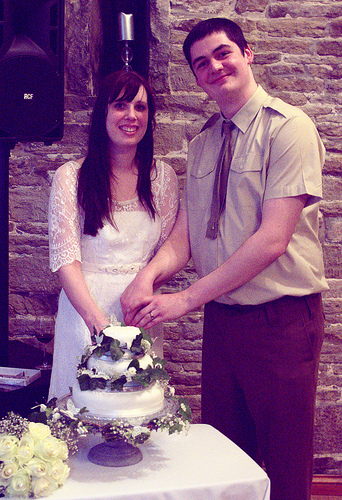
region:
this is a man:
[156, 23, 340, 302]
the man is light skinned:
[212, 250, 263, 298]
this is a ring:
[148, 311, 156, 321]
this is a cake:
[78, 312, 182, 432]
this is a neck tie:
[207, 139, 228, 215]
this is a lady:
[60, 58, 182, 449]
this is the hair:
[83, 142, 101, 198]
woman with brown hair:
[78, 52, 159, 224]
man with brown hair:
[170, 12, 260, 110]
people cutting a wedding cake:
[58, 308, 182, 434]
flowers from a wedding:
[0, 401, 81, 495]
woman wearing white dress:
[31, 75, 186, 384]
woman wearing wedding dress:
[42, 50, 185, 375]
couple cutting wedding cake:
[25, 8, 324, 377]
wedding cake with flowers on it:
[50, 300, 201, 462]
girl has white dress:
[65, 153, 171, 389]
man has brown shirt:
[176, 103, 332, 318]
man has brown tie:
[204, 106, 246, 258]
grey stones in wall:
[254, 1, 339, 76]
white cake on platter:
[27, 321, 197, 440]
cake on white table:
[32, 328, 187, 473]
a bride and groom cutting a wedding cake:
[50, 15, 322, 464]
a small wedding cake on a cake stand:
[56, 322, 181, 467]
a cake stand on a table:
[58, 393, 179, 468]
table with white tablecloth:
[30, 422, 269, 498]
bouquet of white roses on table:
[2, 413, 70, 498]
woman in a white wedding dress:
[48, 72, 178, 397]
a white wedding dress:
[50, 159, 179, 398]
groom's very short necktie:
[209, 122, 246, 238]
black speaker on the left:
[5, 5, 66, 144]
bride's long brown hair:
[80, 71, 157, 236]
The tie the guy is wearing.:
[204, 118, 236, 235]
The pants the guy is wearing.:
[193, 303, 322, 489]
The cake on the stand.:
[62, 319, 173, 415]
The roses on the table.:
[0, 416, 62, 497]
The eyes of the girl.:
[112, 103, 143, 108]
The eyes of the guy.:
[192, 48, 232, 69]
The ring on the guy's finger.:
[149, 310, 157, 318]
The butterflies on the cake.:
[51, 321, 184, 423]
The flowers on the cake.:
[69, 322, 163, 411]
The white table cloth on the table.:
[19, 406, 276, 495]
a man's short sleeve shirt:
[183, 91, 328, 305]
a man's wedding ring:
[147, 311, 157, 319]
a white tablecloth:
[49, 418, 273, 498]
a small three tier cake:
[64, 319, 166, 414]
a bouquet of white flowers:
[0, 417, 73, 496]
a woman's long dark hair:
[76, 63, 165, 235]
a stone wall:
[147, 1, 340, 474]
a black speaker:
[2, 0, 66, 148]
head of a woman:
[95, 72, 151, 149]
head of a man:
[187, 17, 253, 99]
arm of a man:
[182, 119, 311, 313]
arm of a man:
[134, 209, 190, 285]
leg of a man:
[204, 342, 254, 456]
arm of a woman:
[52, 174, 97, 318]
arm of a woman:
[157, 168, 176, 236]